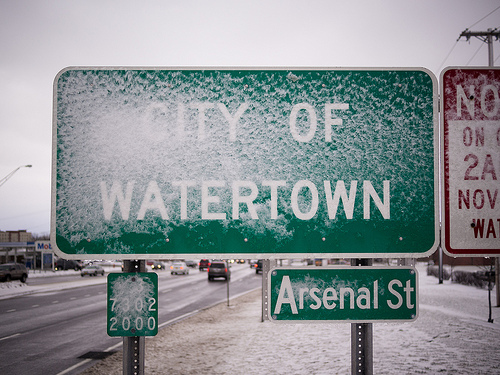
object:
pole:
[120, 257, 151, 374]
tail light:
[178, 266, 185, 269]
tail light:
[168, 265, 175, 270]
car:
[170, 263, 193, 275]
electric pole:
[458, 25, 500, 307]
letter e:
[197, 177, 229, 223]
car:
[204, 259, 234, 283]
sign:
[435, 62, 500, 260]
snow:
[50, 68, 435, 243]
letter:
[141, 97, 172, 150]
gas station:
[0, 229, 72, 280]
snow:
[79, 285, 500, 374]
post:
[346, 254, 381, 373]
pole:
[256, 253, 277, 323]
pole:
[225, 257, 234, 305]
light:
[0, 160, 36, 190]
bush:
[424, 263, 449, 282]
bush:
[452, 266, 497, 290]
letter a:
[131, 180, 173, 223]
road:
[0, 264, 265, 374]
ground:
[0, 263, 500, 374]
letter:
[169, 97, 191, 148]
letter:
[213, 99, 252, 147]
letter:
[96, 177, 137, 222]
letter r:
[228, 176, 263, 222]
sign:
[47, 65, 441, 266]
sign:
[102, 269, 160, 338]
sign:
[264, 263, 423, 325]